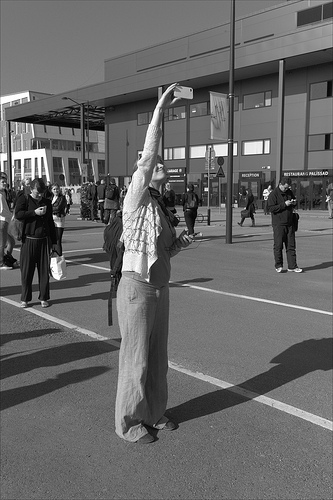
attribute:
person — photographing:
[113, 79, 188, 444]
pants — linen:
[116, 270, 177, 447]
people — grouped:
[75, 177, 120, 229]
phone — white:
[171, 83, 196, 100]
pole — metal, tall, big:
[226, 1, 234, 242]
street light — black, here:
[62, 97, 89, 183]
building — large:
[0, 90, 105, 207]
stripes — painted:
[0, 257, 332, 431]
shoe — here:
[130, 432, 156, 444]